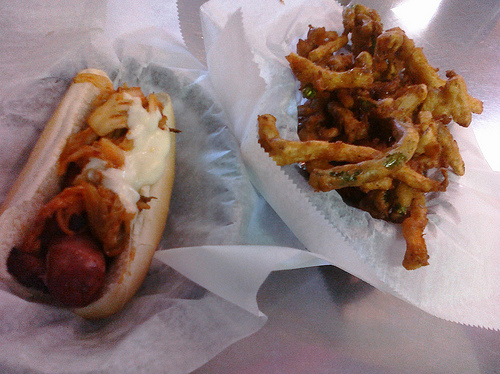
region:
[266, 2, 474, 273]
fried food in paper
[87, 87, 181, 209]
white sauce on a hot dog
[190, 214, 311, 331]
white paper under the hot dog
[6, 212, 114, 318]
a hot dog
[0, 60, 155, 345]
a hot dog with toppings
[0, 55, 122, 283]
hot dog bun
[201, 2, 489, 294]
tray of fried food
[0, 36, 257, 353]
a black tray under the paper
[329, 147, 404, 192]
a green food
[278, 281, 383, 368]
silver table under the food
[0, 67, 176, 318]
brown and white hot dog bun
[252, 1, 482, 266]
deep fried food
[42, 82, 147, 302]
hot dog in bun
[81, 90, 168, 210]
white cheese on hot dog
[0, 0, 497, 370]
white paper holding food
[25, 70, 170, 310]
toppings on hot dog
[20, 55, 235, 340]
black dish holding white paper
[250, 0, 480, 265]
green and brown food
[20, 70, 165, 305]
condiments on food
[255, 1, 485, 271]
golden brown deep fried side dish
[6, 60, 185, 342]
Hot dog on a white paper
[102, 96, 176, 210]
mayonnaise over of a hot dog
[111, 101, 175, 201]
mayonnaise is white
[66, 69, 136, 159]
pieces of onions on hot dog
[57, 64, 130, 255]
onions are wrapped with red souce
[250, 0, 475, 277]
a bunch of fried food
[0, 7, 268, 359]
a white paper underneath the a bun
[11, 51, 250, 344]
a hot dog on a basket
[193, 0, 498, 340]
paper under food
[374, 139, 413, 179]
green vegetable on fried food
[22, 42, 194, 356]
a sandwich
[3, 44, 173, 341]
Hot dog on a bun.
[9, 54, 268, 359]
Hotdog sitting in a basket.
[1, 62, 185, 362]
A hotdog with fixings.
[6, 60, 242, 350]
The hotdog is eady to eat.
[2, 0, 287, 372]
Tissue paper beneath a hotdog.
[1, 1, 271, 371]
Tissue paper is white.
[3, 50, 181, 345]
The hotdog has bacon on it.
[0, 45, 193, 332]
The hotdog has been cooked.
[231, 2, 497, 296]
A side of fried asparagus.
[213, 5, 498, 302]
Fried asparagus in a basket.